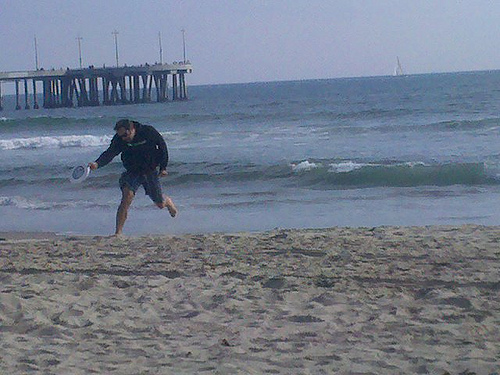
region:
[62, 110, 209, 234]
Man holding white frisbee in his right hand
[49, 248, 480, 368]
Sand filled with footprints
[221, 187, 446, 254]
Shore line with small ripples in the water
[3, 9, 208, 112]
Large pier overlooking the water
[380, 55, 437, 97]
White sail boat on the water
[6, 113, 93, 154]
Larger white waves on the water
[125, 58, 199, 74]
People standing on the pier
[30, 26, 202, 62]
Light poles mounted on the pier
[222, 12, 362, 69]
Clear blue sky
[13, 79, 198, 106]
Bases holding pier above the water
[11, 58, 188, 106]
pier above the ocean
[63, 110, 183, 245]
man playing frisbee on the beach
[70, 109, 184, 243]
man with no shoes on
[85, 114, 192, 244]
man wearing shorts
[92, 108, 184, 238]
man wearing a hoodie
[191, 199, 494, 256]
where the sand and ocean meet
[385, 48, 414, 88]
sailboat in the ocean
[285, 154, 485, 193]
small wave in the ocean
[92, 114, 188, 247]
man playing in the sand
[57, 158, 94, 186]
a round white frisbee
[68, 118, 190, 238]
man catching frisbee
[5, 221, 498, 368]
sand on beach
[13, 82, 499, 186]
ocean breaking at shore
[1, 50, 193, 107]
pier from beach into ocean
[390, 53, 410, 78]
sailboat sailing in distance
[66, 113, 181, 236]
man bending to catch frisbee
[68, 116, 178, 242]
man playing frisbee on beach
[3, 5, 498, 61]
sky in background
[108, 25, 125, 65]
light pole on pier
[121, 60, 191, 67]
people on pier looking out over water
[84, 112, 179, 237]
Guy on beach catching frisbee.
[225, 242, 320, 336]
Many divots in the sand.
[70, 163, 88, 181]
white frisbee in mans hand.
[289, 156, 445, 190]
waves in the ocean.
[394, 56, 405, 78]
Sailboat on the horizon.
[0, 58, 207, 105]
Long pier over the water.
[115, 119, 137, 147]
Mans head that has sunglasses on.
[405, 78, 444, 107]
Blue colored ocean water.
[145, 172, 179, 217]
Left leg of a man.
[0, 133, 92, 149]
Waves in the water.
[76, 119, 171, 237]
this is a man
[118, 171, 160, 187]
the man is wearing shorts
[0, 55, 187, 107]
this is a bridge on the sea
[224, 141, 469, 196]
the sea has small waves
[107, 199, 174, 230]
the man is bare footed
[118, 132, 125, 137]
the man has goggles on t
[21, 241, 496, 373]
the place has sand all over